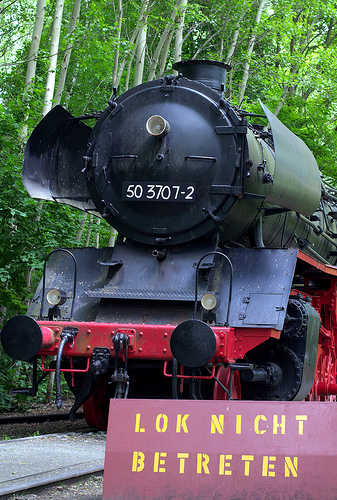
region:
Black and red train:
[10, 48, 336, 443]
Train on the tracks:
[0, 45, 333, 424]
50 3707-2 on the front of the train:
[119, 177, 215, 210]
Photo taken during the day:
[16, 19, 326, 487]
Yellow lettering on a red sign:
[101, 397, 322, 481]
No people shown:
[3, 11, 330, 478]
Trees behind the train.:
[11, 12, 322, 368]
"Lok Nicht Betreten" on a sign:
[115, 400, 312, 484]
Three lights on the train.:
[47, 101, 250, 325]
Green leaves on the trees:
[0, 8, 330, 177]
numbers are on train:
[110, 165, 216, 222]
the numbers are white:
[117, 178, 212, 229]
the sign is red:
[105, 380, 332, 496]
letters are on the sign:
[130, 405, 333, 490]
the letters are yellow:
[120, 407, 319, 487]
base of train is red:
[29, 301, 335, 404]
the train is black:
[9, 77, 306, 317]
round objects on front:
[8, 299, 265, 388]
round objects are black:
[7, 302, 234, 387]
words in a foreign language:
[128, 409, 335, 492]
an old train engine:
[0, 42, 334, 402]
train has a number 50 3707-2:
[103, 159, 218, 220]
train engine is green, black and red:
[11, 48, 335, 395]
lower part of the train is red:
[12, 303, 334, 402]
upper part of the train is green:
[78, 76, 335, 254]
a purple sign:
[94, 390, 332, 497]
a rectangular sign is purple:
[95, 392, 330, 497]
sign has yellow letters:
[90, 394, 330, 497]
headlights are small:
[35, 281, 228, 318]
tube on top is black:
[169, 43, 240, 92]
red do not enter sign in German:
[107, 396, 334, 494]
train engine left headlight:
[194, 286, 216, 310]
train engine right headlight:
[42, 282, 59, 301]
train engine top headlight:
[141, 111, 166, 135]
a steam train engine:
[15, 51, 330, 397]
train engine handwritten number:
[121, 179, 195, 204]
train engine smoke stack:
[165, 51, 231, 92]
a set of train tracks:
[1, 418, 114, 495]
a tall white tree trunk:
[22, 1, 46, 240]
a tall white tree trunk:
[132, 26, 145, 86]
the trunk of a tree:
[43, 24, 64, 99]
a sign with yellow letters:
[110, 399, 328, 498]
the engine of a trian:
[25, 50, 326, 387]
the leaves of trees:
[289, 59, 331, 113]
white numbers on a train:
[122, 173, 203, 205]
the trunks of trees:
[124, 14, 188, 50]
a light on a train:
[195, 290, 221, 317]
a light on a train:
[42, 282, 67, 311]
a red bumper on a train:
[6, 308, 238, 360]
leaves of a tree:
[24, 214, 73, 248]